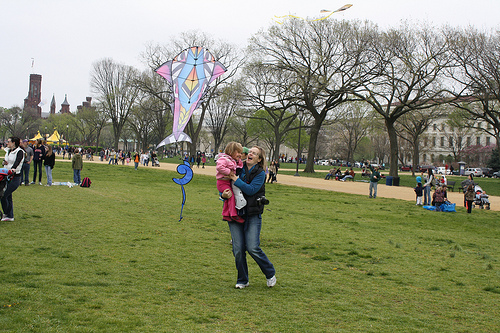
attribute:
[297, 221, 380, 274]
grass — green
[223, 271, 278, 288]
shoe — woman's, white, tennis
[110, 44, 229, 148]
kite — large, colorful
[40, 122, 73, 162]
tent — large, yellow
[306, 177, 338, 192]
road — brown, dirt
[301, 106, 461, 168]
building — white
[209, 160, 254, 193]
coat — girl's, pink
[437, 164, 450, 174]
vehicle — white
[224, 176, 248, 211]
vest — white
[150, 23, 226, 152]
kite — multi color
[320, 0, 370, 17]
yellow kite — in the sky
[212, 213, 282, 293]
jean — blue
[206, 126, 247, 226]
woman — holding a child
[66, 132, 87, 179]
jocket — green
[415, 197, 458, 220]
blue backback — on the ground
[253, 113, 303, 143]
leaves — on the ground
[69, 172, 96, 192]
backpack — on the ground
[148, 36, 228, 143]
kite — fish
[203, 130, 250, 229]
woman — holding a girl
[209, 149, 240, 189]
girl's coat — pink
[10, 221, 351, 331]
grass — green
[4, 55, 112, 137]
buildings — in the background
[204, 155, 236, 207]
jacket — pink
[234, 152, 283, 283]
shirt — blue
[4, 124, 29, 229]
shirt — black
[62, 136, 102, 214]
jacket — green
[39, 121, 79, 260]
jacket — black